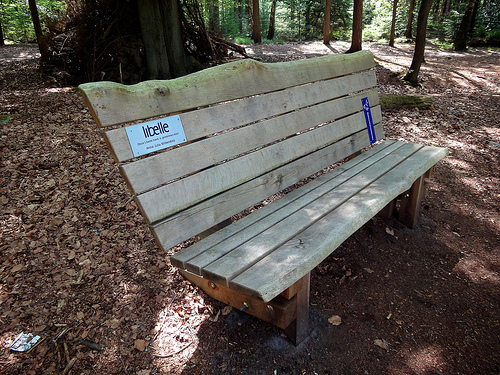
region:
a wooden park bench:
[75, 48, 451, 344]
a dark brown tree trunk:
[412, 0, 430, 69]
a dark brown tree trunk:
[323, 0, 331, 43]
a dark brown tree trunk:
[250, 1, 261, 43]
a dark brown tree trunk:
[267, 0, 277, 37]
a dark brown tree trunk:
[28, 0, 45, 52]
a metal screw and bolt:
[238, 301, 248, 313]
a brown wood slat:
[230, 146, 448, 303]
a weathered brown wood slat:
[203, 142, 421, 285]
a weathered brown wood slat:
[185, 139, 406, 274]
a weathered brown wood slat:
[150, 122, 383, 254]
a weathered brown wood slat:
[135, 104, 382, 223]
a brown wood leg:
[394, 173, 425, 226]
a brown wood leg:
[280, 276, 312, 343]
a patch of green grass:
[381, 93, 428, 108]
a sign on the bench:
[122, 112, 188, 152]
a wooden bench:
[80, 58, 455, 343]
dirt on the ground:
[356, 300, 429, 344]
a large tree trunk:
[46, 23, 214, 63]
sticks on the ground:
[148, 340, 213, 367]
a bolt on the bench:
[238, 305, 254, 310]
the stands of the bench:
[403, 182, 420, 222]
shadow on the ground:
[371, 33, 449, 75]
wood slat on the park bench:
[75, 43, 375, 129]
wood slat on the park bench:
[100, 67, 376, 162]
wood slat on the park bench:
[120, 83, 378, 193]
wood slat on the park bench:
[133, 100, 380, 225]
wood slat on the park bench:
[166, 133, 396, 268]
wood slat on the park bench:
[230, 138, 448, 301]